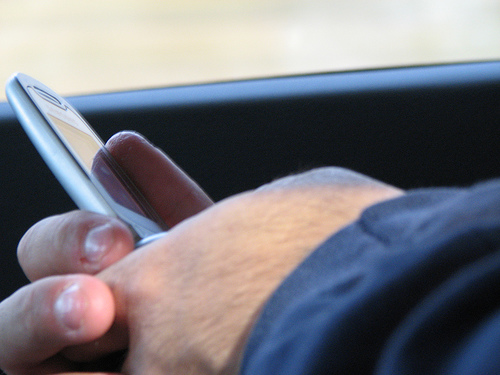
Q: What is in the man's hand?
A: A phone.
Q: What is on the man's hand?
A: Hair.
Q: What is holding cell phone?
A: Man's hands.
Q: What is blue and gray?
A: Sweatshirt sleeve.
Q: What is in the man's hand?
A: Cell phone screen.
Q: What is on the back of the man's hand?
A: Black hair.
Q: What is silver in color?
A: Cell phone.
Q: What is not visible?
A: The man's head.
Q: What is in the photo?
A: Hands and a phone.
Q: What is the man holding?
A: Phone.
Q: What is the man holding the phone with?
A: Hand.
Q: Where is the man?
A: Car.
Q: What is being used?
A: Phone.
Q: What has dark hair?
A: Hand.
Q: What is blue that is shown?
A: Sleeve.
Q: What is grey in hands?
A: Cell phone.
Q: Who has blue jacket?
A: The man.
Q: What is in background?
A: Windowsill of car.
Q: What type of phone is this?
A: Silver touchscreen.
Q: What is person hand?
A: Call phone.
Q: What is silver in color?
A: The phone.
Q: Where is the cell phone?
A: In hand.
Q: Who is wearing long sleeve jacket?
A: The person.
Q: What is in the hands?
A: A cell phone.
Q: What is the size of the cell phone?
A: Small.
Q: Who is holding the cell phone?
A: A man.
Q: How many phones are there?
A: One.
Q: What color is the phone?
A: Silver.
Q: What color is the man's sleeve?
A: Blue.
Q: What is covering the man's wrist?
A: Sleeve.